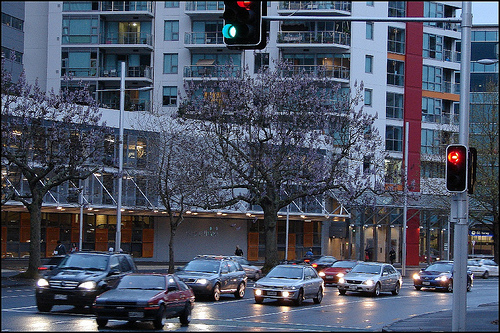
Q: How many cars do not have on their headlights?
A: One.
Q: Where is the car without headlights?
A: In the front.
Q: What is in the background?
A: Buildings.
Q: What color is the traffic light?
A: Green.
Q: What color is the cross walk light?
A: Red.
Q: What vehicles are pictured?
A: Cars.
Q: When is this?
A: Dusk.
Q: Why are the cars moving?
A: The light is green.